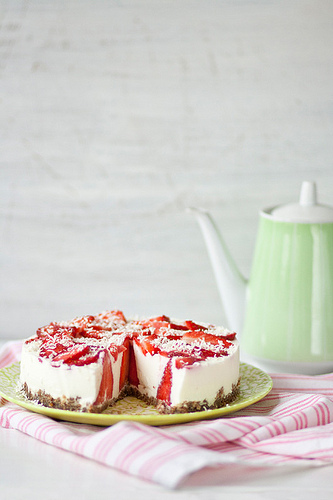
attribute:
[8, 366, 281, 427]
plate — light green and white, speckled , for dessert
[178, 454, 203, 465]
portion tablecloth — white, of tablecloth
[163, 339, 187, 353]
cake — with white sprinkles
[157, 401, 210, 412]
crust — graham cracker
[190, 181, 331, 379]
jug — green and white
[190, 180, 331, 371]
teapot — light green and white, tall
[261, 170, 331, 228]
lid — white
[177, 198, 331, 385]
jug — green 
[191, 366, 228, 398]
surface — cream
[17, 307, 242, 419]
cake — white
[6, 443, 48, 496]
table top — shiny , white , table's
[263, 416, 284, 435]
stripes — red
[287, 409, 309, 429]
stripes — red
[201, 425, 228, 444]
stripes — red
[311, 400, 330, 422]
stripes — red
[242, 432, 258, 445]
stripes — red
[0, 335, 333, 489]
towel — white , for tea , with pink stripes